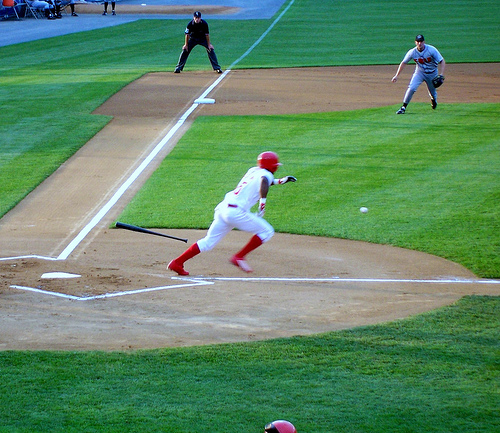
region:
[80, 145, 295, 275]
batter running after dropping bat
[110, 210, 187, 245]
black bat lying on dirt and grass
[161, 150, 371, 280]
white baseball ahead of player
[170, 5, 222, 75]
umpire with hands on knees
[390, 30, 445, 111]
player running forward with mitt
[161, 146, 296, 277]
batter with red helmet, shoes and socks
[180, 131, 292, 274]
A baseball playing launching into a run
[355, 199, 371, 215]
A baseball moving through the air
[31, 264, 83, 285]
A white home plate in the sand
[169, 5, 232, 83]
An umpire stooping with his hands on his knees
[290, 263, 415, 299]
A white stripe on a dirt surface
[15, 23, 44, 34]
Light blue patch of ground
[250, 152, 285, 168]
A red batter's helmet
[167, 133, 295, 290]
baseball batter running to the base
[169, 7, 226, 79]
third baseman watching the play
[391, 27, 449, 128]
baseball player going after the ball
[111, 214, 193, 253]
black baseball bat falling to the ground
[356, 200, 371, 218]
white baseball flying in the air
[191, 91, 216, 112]
white third base in the dirt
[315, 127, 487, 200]
very green grass of the baseball field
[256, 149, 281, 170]
red helmet of the baseball player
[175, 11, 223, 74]
an umpire dressed in black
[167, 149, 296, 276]
baseball player in a red and white uniform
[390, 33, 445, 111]
baseball player wearing a blue hat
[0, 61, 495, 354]
dirt section on the field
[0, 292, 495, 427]
patch of green grass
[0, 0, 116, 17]
spectators to the side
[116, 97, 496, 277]
patch of grass in the middle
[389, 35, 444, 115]
guy in gray and red uniform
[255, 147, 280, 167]
a red shiny helmet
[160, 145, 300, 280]
A baseball player is about to run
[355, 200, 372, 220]
A round and white baseball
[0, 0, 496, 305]
White lines on the field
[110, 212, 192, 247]
A black baseball bat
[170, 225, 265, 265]
A pair of red socks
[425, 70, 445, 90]
A black leather glove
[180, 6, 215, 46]
Umpire wearing a black shirt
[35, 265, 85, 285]
Home plate is white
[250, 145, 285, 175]
A red colored helmet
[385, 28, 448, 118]
Baseball player wearing a gray uniform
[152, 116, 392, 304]
a man playign baseball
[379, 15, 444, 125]
a man paying baseball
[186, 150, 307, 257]
a man on a basball field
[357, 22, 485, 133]
a man on a baseball field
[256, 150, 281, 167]
helmet is red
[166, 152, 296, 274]
man is running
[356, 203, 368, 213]
ball is in the air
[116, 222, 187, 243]
bat is in the air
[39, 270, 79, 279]
base is white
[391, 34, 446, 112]
man is standing in field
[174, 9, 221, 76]
man is standing in the field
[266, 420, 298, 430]
helmet is red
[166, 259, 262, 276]
shoes are red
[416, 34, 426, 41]
hat is on mans head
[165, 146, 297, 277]
Baseball player running down first base path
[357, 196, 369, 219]
Baseball in the grass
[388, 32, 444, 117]
Infielder running to the baseball